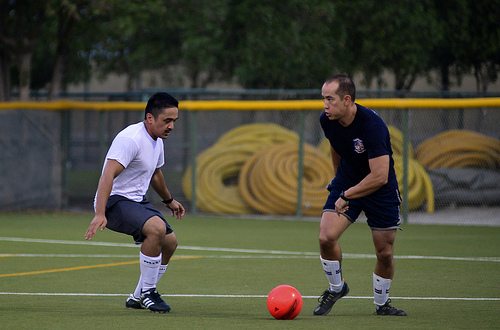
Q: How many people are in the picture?
A: Two.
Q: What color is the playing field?
A: Green.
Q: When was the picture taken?
A: Daytime.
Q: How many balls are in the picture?
A: One.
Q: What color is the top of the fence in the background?
A: Yellow.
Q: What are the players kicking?
A: A ball.